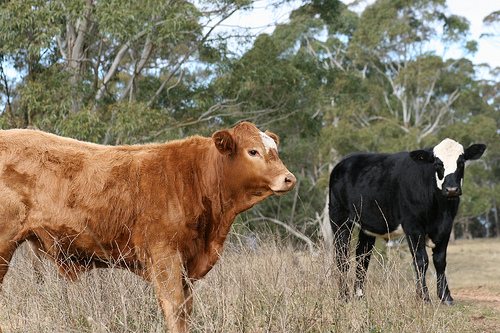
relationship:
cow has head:
[327, 138, 487, 305] [411, 137, 487, 200]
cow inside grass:
[1, 121, 298, 331] [0, 193, 450, 331]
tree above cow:
[1, 0, 318, 145] [1, 121, 298, 331]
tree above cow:
[272, 1, 364, 246] [1, 121, 298, 331]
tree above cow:
[272, 1, 359, 72] [1, 121, 298, 331]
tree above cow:
[328, 0, 499, 247] [1, 121, 298, 331]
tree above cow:
[1, 0, 318, 145] [327, 138, 487, 305]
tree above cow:
[272, 1, 359, 72] [327, 138, 487, 305]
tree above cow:
[272, 1, 364, 246] [327, 138, 487, 305]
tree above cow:
[328, 0, 499, 247] [327, 138, 487, 305]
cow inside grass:
[327, 138, 487, 305] [0, 193, 450, 331]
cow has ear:
[327, 138, 487, 305] [410, 149, 435, 165]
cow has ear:
[327, 138, 487, 305] [465, 143, 487, 161]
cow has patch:
[327, 138, 487, 305] [433, 138, 465, 190]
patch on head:
[433, 138, 465, 190] [411, 137, 487, 200]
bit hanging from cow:
[188, 188, 273, 281] [1, 121, 298, 331]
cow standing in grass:
[1, 121, 298, 331] [0, 193, 450, 331]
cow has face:
[1, 121, 298, 331] [246, 135, 297, 196]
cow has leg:
[327, 138, 487, 305] [404, 226, 431, 302]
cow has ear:
[1, 121, 298, 331] [212, 130, 236, 155]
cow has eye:
[1, 121, 298, 331] [246, 148, 259, 157]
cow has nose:
[327, 138, 487, 305] [444, 185, 460, 196]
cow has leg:
[327, 138, 487, 305] [432, 230, 456, 305]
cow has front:
[327, 138, 487, 305] [405, 139, 488, 305]